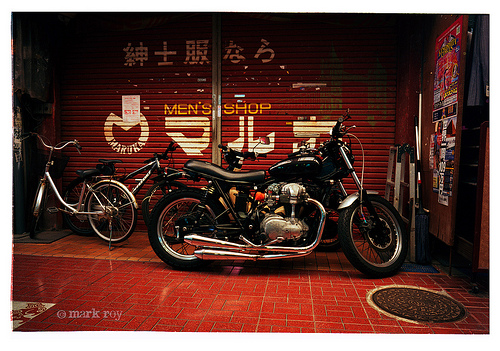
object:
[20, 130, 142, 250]
bicycle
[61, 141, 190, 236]
bicycle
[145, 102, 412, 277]
motorcycle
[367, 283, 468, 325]
man hole cover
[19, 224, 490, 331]
ground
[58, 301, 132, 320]
name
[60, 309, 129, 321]
white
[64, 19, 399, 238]
door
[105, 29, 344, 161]
writing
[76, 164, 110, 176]
seat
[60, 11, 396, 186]
wall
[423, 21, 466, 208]
pictures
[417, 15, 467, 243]
wall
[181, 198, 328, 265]
muffler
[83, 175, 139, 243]
tire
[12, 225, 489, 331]
bricks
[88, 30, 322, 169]
sign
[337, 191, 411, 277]
tire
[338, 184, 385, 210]
fender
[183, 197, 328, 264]
exhaust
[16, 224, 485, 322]
flooring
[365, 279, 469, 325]
man hole covering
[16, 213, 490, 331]
floor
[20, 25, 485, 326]
garage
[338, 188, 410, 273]
wheel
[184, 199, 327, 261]
pipes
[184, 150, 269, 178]
seat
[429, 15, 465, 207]
advertising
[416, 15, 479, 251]
garage door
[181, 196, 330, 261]
exhaust pipes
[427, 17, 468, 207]
posters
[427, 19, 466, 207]
stickers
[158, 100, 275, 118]
lettering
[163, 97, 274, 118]
men's shop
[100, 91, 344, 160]
symbol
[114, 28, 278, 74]
symbols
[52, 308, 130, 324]
watermark